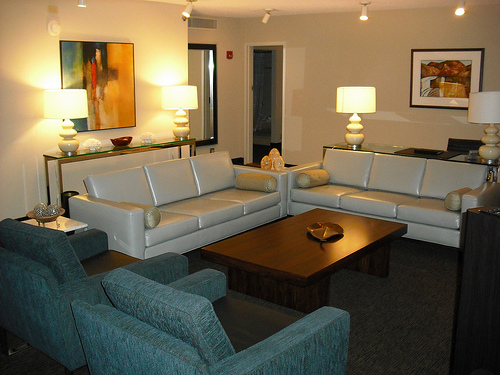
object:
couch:
[67, 150, 288, 261]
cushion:
[200, 187, 280, 214]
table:
[200, 208, 408, 314]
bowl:
[110, 136, 132, 146]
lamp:
[466, 91, 499, 166]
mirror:
[187, 49, 218, 145]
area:
[77, 42, 421, 316]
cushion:
[145, 211, 198, 248]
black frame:
[410, 48, 485, 110]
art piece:
[420, 60, 473, 98]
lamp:
[334, 86, 376, 149]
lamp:
[160, 85, 198, 141]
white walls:
[285, 12, 499, 169]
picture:
[59, 41, 137, 133]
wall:
[0, 0, 190, 217]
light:
[455, 0, 465, 15]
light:
[359, 5, 369, 21]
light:
[261, 12, 270, 25]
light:
[180, 3, 192, 18]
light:
[75, 0, 87, 8]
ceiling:
[0, 0, 500, 24]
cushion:
[157, 197, 245, 230]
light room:
[0, 0, 500, 375]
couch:
[278, 148, 488, 249]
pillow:
[296, 169, 330, 188]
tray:
[307, 221, 344, 241]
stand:
[42, 137, 197, 216]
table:
[246, 161, 297, 168]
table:
[20, 216, 88, 234]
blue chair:
[71, 266, 350, 375]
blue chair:
[0, 218, 190, 372]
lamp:
[43, 89, 89, 157]